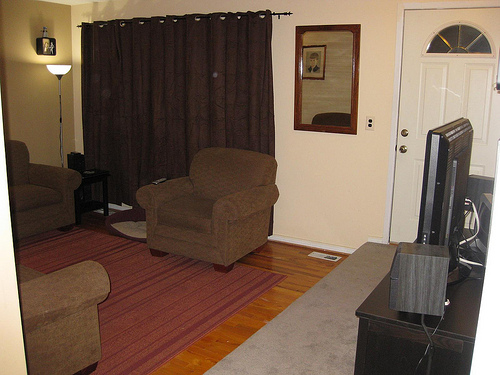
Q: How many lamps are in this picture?
A: One.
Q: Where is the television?
A: On the right.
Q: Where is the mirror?
A: Between the door and the window.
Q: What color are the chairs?
A: Brown.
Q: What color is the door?
A: White.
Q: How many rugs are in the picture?
A: Two.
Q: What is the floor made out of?
A: Hardwood.